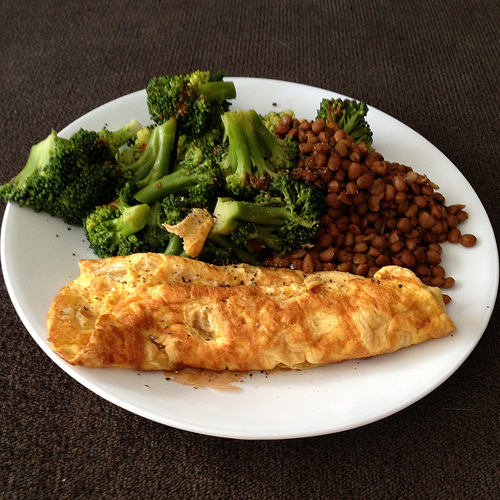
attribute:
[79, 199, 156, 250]
broccoli — green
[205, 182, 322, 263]
broccoli — green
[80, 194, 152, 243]
broccoli — green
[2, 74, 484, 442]
plate — white